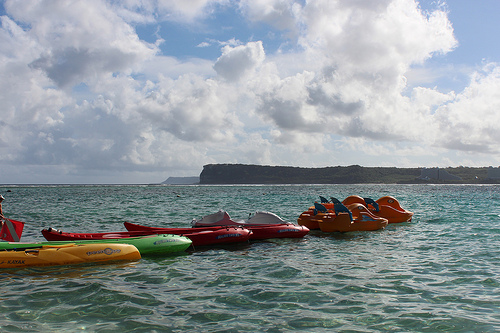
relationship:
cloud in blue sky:
[3, 0, 159, 74] [2, 0, 498, 184]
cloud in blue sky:
[213, 36, 266, 83] [2, 0, 498, 184]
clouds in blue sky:
[299, 8, 442, 94] [2, 0, 498, 184]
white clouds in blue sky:
[435, 86, 497, 151] [2, 0, 498, 184]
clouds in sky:
[0, 0, 497, 185] [0, 0, 497, 184]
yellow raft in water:
[13, 234, 133, 282] [230, 250, 495, 285]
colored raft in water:
[141, 229, 193, 258] [5, 182, 498, 329]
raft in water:
[209, 210, 311, 239] [5, 182, 498, 329]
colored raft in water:
[95, 233, 193, 255] [5, 182, 498, 329]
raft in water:
[287, 201, 387, 233] [5, 182, 498, 329]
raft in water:
[325, 187, 414, 227] [5, 182, 498, 329]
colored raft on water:
[95, 233, 193, 255] [5, 182, 498, 329]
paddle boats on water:
[293, 194, 415, 233] [5, 182, 498, 329]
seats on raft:
[321, 196, 350, 212] [317, 201, 386, 233]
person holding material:
[0, 195, 19, 237] [5, 210, 21, 237]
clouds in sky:
[14, 21, 214, 173] [77, 13, 426, 137]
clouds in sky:
[299, 8, 442, 94] [144, 47, 425, 157]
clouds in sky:
[299, 8, 442, 94] [0, 0, 497, 184]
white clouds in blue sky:
[435, 86, 497, 151] [438, 9, 490, 61]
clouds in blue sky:
[0, 0, 497, 185] [0, 0, 500, 166]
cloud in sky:
[213, 36, 266, 83] [106, 15, 394, 141]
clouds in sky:
[178, 65, 333, 142] [54, 49, 424, 145]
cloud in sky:
[1, 57, 70, 147] [80, 43, 407, 105]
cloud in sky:
[213, 36, 266, 83] [0, 0, 497, 184]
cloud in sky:
[41, 94, 166, 141] [0, 0, 497, 184]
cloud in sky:
[434, 63, 497, 151] [0, 0, 497, 184]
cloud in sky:
[161, 0, 215, 26] [0, 0, 497, 184]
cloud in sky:
[229, 133, 271, 164] [0, 0, 497, 184]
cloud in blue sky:
[1, 57, 70, 147] [151, 22, 498, 88]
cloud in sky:
[3, 0, 159, 74] [0, 0, 497, 184]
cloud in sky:
[1, 57, 70, 147] [0, 0, 497, 184]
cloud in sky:
[131, 74, 238, 145] [0, 0, 497, 184]